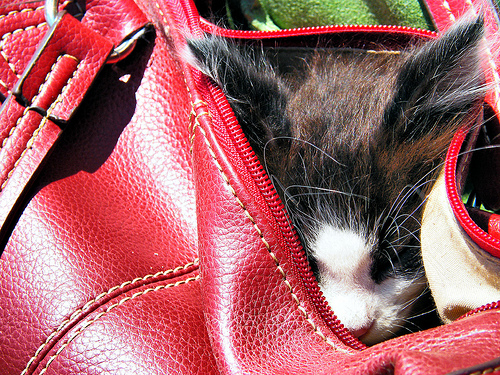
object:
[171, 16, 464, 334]
cat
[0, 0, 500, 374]
bag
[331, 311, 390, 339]
nose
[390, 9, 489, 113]
ears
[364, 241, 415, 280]
eyes